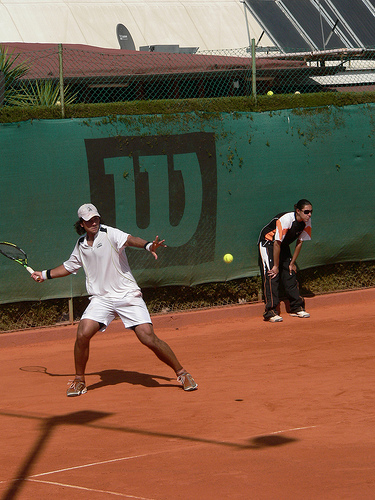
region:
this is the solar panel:
[264, 2, 361, 42]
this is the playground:
[175, 416, 335, 489]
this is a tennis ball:
[218, 250, 236, 268]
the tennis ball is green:
[223, 252, 239, 262]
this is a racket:
[0, 240, 34, 271]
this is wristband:
[42, 270, 51, 280]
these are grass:
[172, 283, 242, 301]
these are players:
[5, 196, 331, 390]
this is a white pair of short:
[79, 296, 154, 324]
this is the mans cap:
[75, 201, 103, 218]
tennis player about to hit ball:
[8, 195, 239, 408]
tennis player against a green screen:
[23, 165, 218, 411]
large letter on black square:
[55, 121, 235, 275]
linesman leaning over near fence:
[250, 173, 325, 332]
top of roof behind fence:
[12, 24, 299, 129]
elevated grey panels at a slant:
[240, 0, 369, 60]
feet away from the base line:
[22, 347, 315, 475]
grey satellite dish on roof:
[91, 5, 137, 56]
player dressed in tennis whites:
[65, 190, 176, 362]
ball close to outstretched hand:
[145, 225, 238, 278]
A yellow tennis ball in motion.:
[213, 248, 241, 268]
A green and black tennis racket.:
[0, 231, 61, 288]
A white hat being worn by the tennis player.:
[70, 199, 109, 226]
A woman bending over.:
[257, 192, 326, 322]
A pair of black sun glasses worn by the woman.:
[294, 206, 315, 218]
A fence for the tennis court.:
[0, 43, 373, 327]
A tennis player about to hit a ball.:
[5, 193, 203, 412]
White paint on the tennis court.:
[4, 413, 366, 498]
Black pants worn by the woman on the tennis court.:
[252, 237, 305, 323]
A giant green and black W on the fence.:
[73, 119, 228, 282]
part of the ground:
[263, 373, 301, 436]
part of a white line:
[50, 474, 92, 495]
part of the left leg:
[155, 338, 174, 362]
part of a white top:
[96, 259, 131, 276]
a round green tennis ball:
[222, 250, 235, 271]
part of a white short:
[112, 304, 135, 327]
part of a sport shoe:
[179, 374, 199, 393]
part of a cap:
[82, 201, 99, 222]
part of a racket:
[11, 254, 35, 272]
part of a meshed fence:
[180, 211, 215, 244]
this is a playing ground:
[218, 330, 334, 392]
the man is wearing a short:
[124, 306, 134, 318]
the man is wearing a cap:
[82, 205, 95, 214]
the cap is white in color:
[83, 203, 92, 214]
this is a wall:
[233, 146, 280, 202]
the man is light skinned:
[135, 239, 142, 243]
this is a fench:
[84, 55, 161, 90]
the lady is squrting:
[260, 200, 308, 318]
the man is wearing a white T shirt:
[91, 259, 128, 287]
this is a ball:
[224, 252, 232, 262]